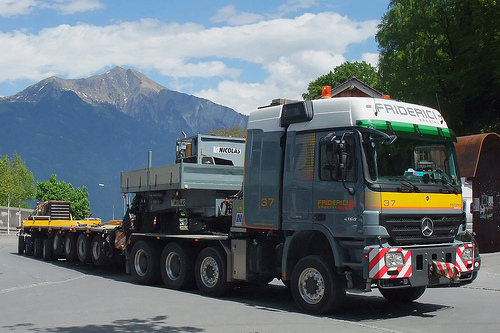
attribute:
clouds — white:
[10, 25, 370, 62]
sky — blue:
[0, 2, 391, 95]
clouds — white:
[1, 12, 383, 115]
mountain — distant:
[10, 56, 281, 243]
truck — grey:
[226, 79, 468, 316]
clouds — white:
[2, 9, 369, 84]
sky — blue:
[2, 3, 380, 70]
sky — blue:
[135, 41, 326, 93]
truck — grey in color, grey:
[16, 84, 481, 314]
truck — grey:
[209, 82, 478, 328]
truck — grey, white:
[7, 70, 485, 320]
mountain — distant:
[0, 66, 249, 222]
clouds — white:
[3, 1, 390, 116]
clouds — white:
[17, 32, 154, 64]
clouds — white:
[162, 62, 239, 77]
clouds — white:
[238, 17, 346, 50]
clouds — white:
[365, 52, 379, 65]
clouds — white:
[275, 50, 331, 67]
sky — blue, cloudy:
[0, 1, 398, 115]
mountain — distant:
[31, 56, 166, 141]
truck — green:
[3, 133, 467, 315]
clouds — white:
[3, 26, 343, 71]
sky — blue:
[94, 2, 284, 29]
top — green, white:
[248, 97, 451, 137]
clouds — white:
[0, 19, 381, 89]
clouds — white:
[226, 27, 308, 77]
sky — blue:
[3, 5, 379, 76]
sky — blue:
[4, 1, 384, 105]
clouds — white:
[8, 4, 338, 85]